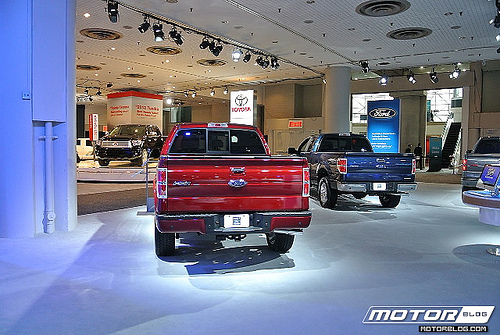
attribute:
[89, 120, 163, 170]
truck — Toyota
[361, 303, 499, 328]
sign — motor blog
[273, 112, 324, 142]
sign — Exit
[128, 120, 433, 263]
trucks — red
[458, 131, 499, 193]
truck — silver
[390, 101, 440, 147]
ground — red, ford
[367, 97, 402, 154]
sign — Hanging 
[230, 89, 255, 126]
sign — Hanging 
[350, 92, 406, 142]
ground — white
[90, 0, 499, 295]
room — show, automobile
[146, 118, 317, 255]
truck — red, black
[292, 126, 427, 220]
truck — large, blue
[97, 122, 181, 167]
truck — new, black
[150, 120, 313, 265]
truck — new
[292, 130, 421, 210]
truck — blue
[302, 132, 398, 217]
truck — blue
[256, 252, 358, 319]
floor — bright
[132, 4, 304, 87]
lights — stage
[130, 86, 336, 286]
truck — large